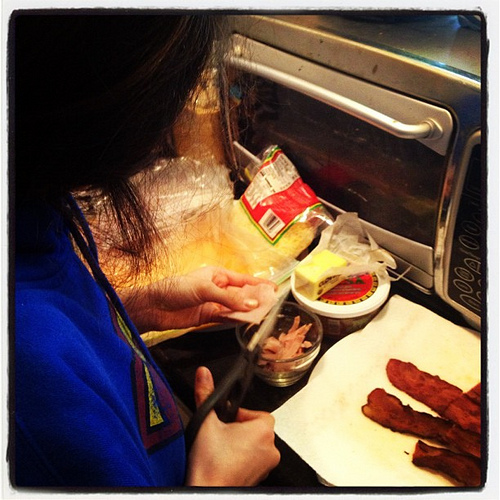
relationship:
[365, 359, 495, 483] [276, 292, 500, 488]
bacon strips are on top of cutting board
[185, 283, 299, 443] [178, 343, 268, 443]
scissors have a handle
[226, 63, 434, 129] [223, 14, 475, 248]
bar handle in front of oven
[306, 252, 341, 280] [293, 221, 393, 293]
butter stick covered by wrapper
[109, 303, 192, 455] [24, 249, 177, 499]
emblem printed on shirt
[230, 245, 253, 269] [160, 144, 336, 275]
shredded cheese inside a bag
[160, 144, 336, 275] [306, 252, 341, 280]
bag to left of butter stick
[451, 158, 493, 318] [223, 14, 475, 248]
touch controls are in front of oven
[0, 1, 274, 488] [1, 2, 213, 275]
person has hair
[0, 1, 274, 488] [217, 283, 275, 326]
person cutting meat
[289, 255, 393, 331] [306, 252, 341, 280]
sa container under butter stick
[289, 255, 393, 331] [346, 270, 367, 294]
sa container has partial letterin sa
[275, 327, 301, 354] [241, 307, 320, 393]
meat strips are inside glass container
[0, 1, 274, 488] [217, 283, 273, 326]
woman cutting meat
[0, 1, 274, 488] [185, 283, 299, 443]
woman holding scissors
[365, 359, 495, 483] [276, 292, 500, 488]
bacon strips are lying on top of paper towel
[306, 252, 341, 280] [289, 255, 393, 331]
butter stick on top of a sa container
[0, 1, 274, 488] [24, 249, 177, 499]
woman wearing a shirt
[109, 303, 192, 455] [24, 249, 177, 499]
superman logo on shirt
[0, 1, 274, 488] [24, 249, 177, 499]
woman wearing shirt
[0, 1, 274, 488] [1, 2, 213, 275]
woman has hair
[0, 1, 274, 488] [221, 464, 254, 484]
lady has skin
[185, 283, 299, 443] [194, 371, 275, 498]
scissors in a hand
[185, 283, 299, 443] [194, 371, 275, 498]
scissors are in hand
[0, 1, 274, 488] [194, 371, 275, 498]
person has a hand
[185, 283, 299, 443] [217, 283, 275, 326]
scissors are used to cut ham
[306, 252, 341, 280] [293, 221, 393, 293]
butter stick partly outside wrapper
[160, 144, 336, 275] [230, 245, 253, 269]
bag full of shredded cheese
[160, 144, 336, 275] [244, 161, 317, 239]
bag has food label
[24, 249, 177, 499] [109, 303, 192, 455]
sweater has superman logo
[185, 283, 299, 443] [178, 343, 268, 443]
scissors has handle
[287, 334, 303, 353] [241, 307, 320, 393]
meat strips inside cup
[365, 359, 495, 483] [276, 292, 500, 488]
bacon strips sit upon a cutting board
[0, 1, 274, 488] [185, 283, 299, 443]
woman using scissors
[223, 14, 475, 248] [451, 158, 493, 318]
oven have touch controls